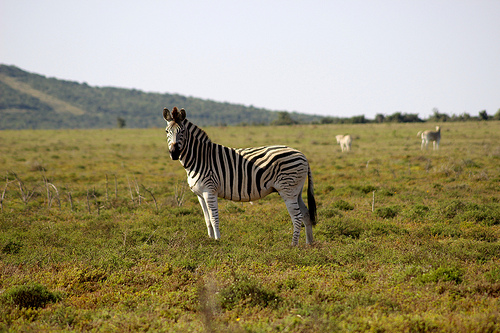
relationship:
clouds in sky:
[419, 25, 475, 92] [8, 10, 485, 109]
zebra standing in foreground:
[160, 106, 321, 249] [2, 104, 483, 328]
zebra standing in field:
[160, 106, 321, 249] [1, 119, 484, 330]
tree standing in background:
[270, 109, 298, 125] [0, 62, 481, 128]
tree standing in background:
[372, 110, 385, 121] [0, 62, 481, 128]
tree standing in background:
[477, 109, 485, 120] [0, 62, 481, 128]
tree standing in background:
[308, 118, 321, 125] [0, 62, 481, 128]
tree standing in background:
[117, 115, 126, 129] [0, 62, 481, 128]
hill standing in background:
[1, 63, 348, 128] [0, 62, 481, 128]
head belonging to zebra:
[162, 106, 189, 160] [160, 106, 321, 249]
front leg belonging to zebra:
[194, 192, 214, 239] [160, 106, 321, 249]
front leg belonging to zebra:
[201, 188, 221, 243] [160, 106, 321, 249]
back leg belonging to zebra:
[277, 183, 303, 246] [160, 106, 321, 249]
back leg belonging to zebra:
[295, 190, 315, 246] [160, 106, 321, 249]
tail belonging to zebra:
[306, 163, 318, 227] [160, 106, 321, 249]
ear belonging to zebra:
[162, 107, 171, 123] [160, 106, 321, 249]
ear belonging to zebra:
[177, 108, 187, 123] [160, 106, 321, 249]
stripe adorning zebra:
[253, 150, 304, 200] [160, 106, 321, 249]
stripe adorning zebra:
[236, 145, 246, 203] [160, 106, 321, 249]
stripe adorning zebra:
[223, 144, 235, 200] [160, 106, 321, 249]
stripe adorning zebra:
[210, 140, 222, 184] [160, 106, 321, 249]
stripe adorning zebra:
[290, 200, 299, 203] [160, 106, 321, 249]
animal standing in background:
[334, 130, 354, 150] [2, 61, 484, 158]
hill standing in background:
[1, 63, 348, 128] [2, 61, 484, 158]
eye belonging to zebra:
[179, 128, 186, 135] [160, 106, 321, 249]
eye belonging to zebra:
[177, 128, 181, 134] [160, 106, 321, 249]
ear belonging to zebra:
[161, 106, 171, 125] [160, 106, 321, 249]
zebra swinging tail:
[160, 106, 321, 249] [304, 160, 317, 228]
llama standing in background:
[414, 122, 441, 152] [2, 61, 484, 158]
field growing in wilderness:
[1, 119, 484, 330] [2, 63, 484, 327]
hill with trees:
[0, 63, 348, 128] [3, 62, 345, 126]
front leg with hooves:
[196, 189, 213, 234] [206, 234, 318, 244]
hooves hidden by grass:
[206, 234, 318, 244] [3, 130, 484, 328]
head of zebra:
[162, 109, 190, 159] [160, 106, 321, 249]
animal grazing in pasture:
[335, 134, 353, 152] [3, 127, 483, 324]